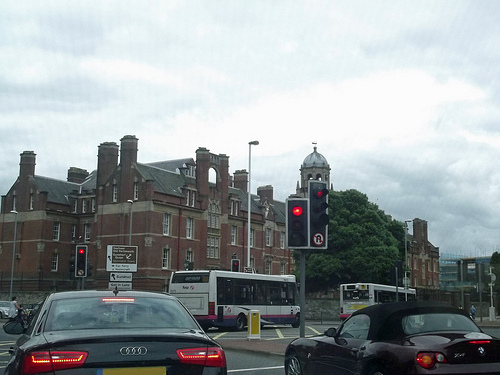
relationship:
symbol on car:
[11, 268, 234, 373] [66, 260, 245, 372]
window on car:
[42, 296, 201, 332] [13, 286, 230, 372]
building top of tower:
[299, 141, 331, 170] [295, 140, 333, 194]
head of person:
[10, 291, 20, 303] [4, 292, 32, 334]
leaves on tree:
[336, 210, 345, 245] [291, 189, 410, 282]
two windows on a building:
[151, 211, 211, 243] [0, 131, 302, 289]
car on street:
[285, 302, 500, 375] [5, 275, 498, 373]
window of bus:
[220, 271, 234, 308] [168, 264, 304, 334]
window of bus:
[237, 277, 253, 303] [168, 264, 304, 334]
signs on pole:
[103, 242, 141, 287] [122, 290, 129, 324]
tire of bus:
[238, 310, 251, 328] [153, 228, 338, 330]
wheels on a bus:
[255, 353, 316, 372] [168, 257, 308, 322]